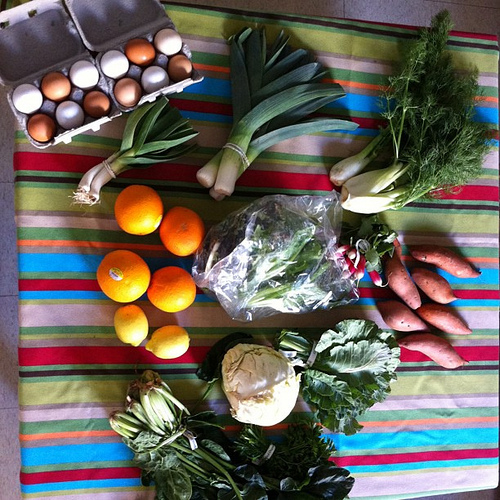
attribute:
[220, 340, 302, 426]
cabbage — green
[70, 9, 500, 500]
vegetables — green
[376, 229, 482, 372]
sweet potatoes — oval, red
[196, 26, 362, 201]
fennel — green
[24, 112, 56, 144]
egg — brown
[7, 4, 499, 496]
fabric — colorful